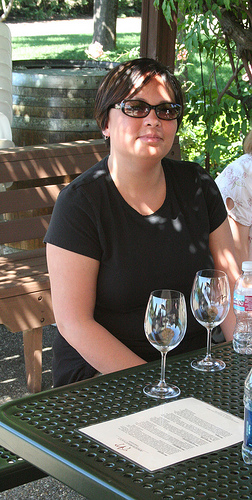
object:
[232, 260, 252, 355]
bottle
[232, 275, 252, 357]
water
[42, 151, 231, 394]
shirt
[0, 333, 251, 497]
table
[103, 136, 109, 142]
earing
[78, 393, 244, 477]
menu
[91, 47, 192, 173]
bananas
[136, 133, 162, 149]
lips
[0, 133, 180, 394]
bench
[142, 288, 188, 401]
glass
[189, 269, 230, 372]
glass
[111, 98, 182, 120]
black sunglasses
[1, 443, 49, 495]
bench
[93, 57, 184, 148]
hair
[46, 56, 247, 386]
woman